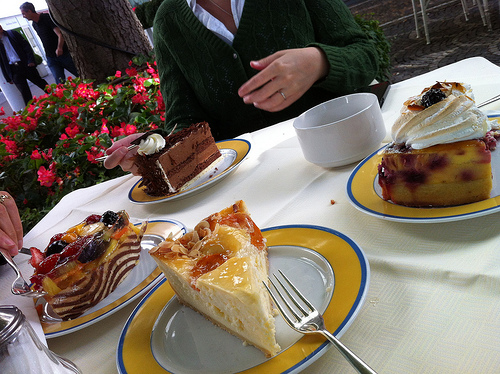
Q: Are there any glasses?
A: No, there are no glasses.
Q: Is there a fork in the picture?
A: Yes, there is a fork.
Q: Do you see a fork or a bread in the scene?
A: Yes, there is a fork.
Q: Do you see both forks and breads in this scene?
A: No, there is a fork but no breads.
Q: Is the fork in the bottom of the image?
A: Yes, the fork is in the bottom of the image.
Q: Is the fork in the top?
A: No, the fork is in the bottom of the image.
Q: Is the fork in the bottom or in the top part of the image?
A: The fork is in the bottom of the image.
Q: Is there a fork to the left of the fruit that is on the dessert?
A: Yes, there is a fork to the left of the fruit.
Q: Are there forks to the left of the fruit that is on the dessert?
A: Yes, there is a fork to the left of the fruit.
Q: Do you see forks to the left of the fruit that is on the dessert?
A: Yes, there is a fork to the left of the fruit.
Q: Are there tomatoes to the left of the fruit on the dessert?
A: No, there is a fork to the left of the fruit.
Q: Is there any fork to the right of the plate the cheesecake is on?
A: No, the fork is to the left of the plate.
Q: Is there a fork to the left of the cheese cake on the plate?
A: Yes, there is a fork to the left of the cheese cake.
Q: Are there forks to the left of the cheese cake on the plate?
A: Yes, there is a fork to the left of the cheese cake.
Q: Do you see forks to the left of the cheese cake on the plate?
A: Yes, there is a fork to the left of the cheese cake.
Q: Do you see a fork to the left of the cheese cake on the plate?
A: Yes, there is a fork to the left of the cheese cake.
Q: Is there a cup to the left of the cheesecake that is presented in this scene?
A: No, there is a fork to the left of the cheesecake.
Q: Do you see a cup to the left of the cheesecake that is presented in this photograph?
A: No, there is a fork to the left of the cheesecake.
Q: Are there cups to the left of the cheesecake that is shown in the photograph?
A: No, there is a fork to the left of the cheesecake.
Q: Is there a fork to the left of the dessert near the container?
A: Yes, there is a fork to the left of the dessert.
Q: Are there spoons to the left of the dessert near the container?
A: No, there is a fork to the left of the dessert.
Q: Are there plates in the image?
A: Yes, there is a plate.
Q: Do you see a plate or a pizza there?
A: Yes, there is a plate.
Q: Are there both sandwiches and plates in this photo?
A: No, there is a plate but no sandwiches.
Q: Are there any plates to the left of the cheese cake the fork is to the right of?
A: Yes, there is a plate to the left of the cheesecake.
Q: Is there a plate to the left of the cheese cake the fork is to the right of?
A: Yes, there is a plate to the left of the cheesecake.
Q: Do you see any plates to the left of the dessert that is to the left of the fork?
A: Yes, there is a plate to the left of the cheesecake.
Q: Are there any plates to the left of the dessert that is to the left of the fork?
A: Yes, there is a plate to the left of the cheesecake.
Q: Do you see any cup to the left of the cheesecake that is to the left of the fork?
A: No, there is a plate to the left of the cheese cake.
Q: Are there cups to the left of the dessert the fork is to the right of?
A: No, there is a plate to the left of the cheese cake.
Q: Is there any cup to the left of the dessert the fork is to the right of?
A: No, there is a plate to the left of the cheese cake.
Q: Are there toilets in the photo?
A: No, there are no toilets.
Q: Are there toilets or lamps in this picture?
A: No, there are no toilets or lamps.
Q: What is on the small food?
A: The icing is on the pie.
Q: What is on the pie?
A: The icing is on the pie.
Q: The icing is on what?
A: The icing is on the pie.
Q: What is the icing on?
A: The icing is on the pie.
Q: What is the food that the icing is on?
A: The food is a pie.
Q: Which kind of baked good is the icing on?
A: The icing is on the pie.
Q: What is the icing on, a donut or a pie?
A: The icing is on a pie.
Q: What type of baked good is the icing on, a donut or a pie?
A: The icing is on a pie.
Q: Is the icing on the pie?
A: Yes, the icing is on the pie.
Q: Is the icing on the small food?
A: Yes, the icing is on the pie.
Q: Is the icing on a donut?
A: No, the icing is on the pie.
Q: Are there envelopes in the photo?
A: No, there are no envelopes.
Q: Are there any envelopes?
A: No, there are no envelopes.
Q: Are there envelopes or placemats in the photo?
A: No, there are no envelopes or placemats.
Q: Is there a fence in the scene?
A: No, there are no fences.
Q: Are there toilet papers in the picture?
A: No, there are no toilet papers.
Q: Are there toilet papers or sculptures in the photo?
A: No, there are no toilet papers or sculptures.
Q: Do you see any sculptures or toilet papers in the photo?
A: No, there are no toilet papers or sculptures.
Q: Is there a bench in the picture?
A: No, there are no benches.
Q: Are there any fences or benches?
A: No, there are no benches or fences.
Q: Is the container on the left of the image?
A: Yes, the container is on the left of the image.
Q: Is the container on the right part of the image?
A: No, the container is on the left of the image.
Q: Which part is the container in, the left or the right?
A: The container is on the left of the image.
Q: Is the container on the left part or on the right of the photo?
A: The container is on the left of the image.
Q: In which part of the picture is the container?
A: The container is on the left of the image.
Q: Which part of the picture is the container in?
A: The container is on the left of the image.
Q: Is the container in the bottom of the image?
A: Yes, the container is in the bottom of the image.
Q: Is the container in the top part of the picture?
A: No, the container is in the bottom of the image.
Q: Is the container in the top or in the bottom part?
A: The container is in the bottom of the image.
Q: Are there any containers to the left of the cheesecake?
A: Yes, there is a container to the left of the cheesecake.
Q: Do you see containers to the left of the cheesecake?
A: Yes, there is a container to the left of the cheesecake.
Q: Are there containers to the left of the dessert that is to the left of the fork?
A: Yes, there is a container to the left of the cheesecake.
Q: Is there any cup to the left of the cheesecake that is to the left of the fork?
A: No, there is a container to the left of the cheese cake.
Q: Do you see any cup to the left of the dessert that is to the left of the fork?
A: No, there is a container to the left of the cheese cake.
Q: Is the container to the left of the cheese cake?
A: Yes, the container is to the left of the cheese cake.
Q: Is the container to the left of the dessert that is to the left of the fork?
A: Yes, the container is to the left of the cheese cake.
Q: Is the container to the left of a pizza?
A: No, the container is to the left of the cheese cake.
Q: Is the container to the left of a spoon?
A: No, the container is to the left of the plate.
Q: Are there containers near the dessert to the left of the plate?
A: Yes, there is a container near the dessert.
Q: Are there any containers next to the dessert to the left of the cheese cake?
A: Yes, there is a container next to the dessert.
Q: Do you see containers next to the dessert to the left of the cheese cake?
A: Yes, there is a container next to the dessert.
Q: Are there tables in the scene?
A: Yes, there is a table.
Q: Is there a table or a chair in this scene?
A: Yes, there is a table.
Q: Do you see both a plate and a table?
A: Yes, there are both a table and a plate.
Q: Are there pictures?
A: No, there are no pictures.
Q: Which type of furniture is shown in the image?
A: The furniture is a table.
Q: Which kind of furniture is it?
A: The piece of furniture is a table.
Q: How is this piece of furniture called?
A: That is a table.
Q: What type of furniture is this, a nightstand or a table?
A: That is a table.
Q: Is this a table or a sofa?
A: This is a table.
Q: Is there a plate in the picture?
A: Yes, there is a plate.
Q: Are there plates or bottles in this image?
A: Yes, there is a plate.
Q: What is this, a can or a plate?
A: This is a plate.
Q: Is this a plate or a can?
A: This is a plate.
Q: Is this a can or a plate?
A: This is a plate.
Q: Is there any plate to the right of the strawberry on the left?
A: Yes, there is a plate to the right of the strawberry.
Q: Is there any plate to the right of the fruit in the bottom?
A: Yes, there is a plate to the right of the strawberry.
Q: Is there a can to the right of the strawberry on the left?
A: No, there is a plate to the right of the strawberry.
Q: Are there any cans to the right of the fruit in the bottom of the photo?
A: No, there is a plate to the right of the strawberry.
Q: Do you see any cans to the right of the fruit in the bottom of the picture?
A: No, there is a plate to the right of the strawberry.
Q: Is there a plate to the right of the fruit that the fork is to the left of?
A: Yes, there is a plate to the right of the fruit.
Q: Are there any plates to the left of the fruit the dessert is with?
A: No, the plate is to the right of the fruit.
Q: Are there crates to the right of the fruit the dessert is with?
A: No, there is a plate to the right of the fruit.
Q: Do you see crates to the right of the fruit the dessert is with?
A: No, there is a plate to the right of the fruit.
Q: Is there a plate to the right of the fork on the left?
A: Yes, there is a plate to the right of the fork.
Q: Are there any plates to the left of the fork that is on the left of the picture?
A: No, the plate is to the right of the fork.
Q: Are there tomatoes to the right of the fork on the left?
A: No, there is a plate to the right of the fork.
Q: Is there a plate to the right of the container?
A: Yes, there is a plate to the right of the container.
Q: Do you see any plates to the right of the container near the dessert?
A: Yes, there is a plate to the right of the container.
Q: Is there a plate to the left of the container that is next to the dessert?
A: No, the plate is to the right of the container.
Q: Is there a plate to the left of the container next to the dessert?
A: No, the plate is to the right of the container.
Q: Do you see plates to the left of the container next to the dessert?
A: No, the plate is to the right of the container.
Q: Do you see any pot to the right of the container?
A: No, there is a plate to the right of the container.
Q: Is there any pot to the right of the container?
A: No, there is a plate to the right of the container.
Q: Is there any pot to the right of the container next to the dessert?
A: No, there is a plate to the right of the container.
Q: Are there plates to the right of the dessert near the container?
A: Yes, there is a plate to the right of the dessert.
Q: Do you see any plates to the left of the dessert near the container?
A: No, the plate is to the right of the dessert.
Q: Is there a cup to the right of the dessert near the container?
A: No, there is a plate to the right of the dessert.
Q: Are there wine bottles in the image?
A: No, there are no wine bottles.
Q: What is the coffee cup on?
A: The coffee cup is on the table.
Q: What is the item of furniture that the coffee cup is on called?
A: The piece of furniture is a table.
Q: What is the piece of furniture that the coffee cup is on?
A: The piece of furniture is a table.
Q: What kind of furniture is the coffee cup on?
A: The coffee cup is on the table.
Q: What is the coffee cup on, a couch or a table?
A: The coffee cup is on a table.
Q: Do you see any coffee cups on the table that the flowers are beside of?
A: Yes, there is a coffee cup on the table.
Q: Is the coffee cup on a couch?
A: No, the coffee cup is on the table.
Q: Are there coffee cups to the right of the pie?
A: Yes, there is a coffee cup to the right of the pie.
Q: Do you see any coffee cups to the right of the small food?
A: Yes, there is a coffee cup to the right of the pie.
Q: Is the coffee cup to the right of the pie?
A: Yes, the coffee cup is to the right of the pie.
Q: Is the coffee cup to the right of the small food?
A: Yes, the coffee cup is to the right of the pie.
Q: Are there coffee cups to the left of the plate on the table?
A: Yes, there is a coffee cup to the left of the plate.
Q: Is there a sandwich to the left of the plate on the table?
A: No, there is a coffee cup to the left of the plate.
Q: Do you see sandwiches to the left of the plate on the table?
A: No, there is a coffee cup to the left of the plate.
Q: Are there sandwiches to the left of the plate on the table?
A: No, there is a coffee cup to the left of the plate.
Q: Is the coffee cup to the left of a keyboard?
A: No, the coffee cup is to the left of the plate.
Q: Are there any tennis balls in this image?
A: No, there are no tennis balls.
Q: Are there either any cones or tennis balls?
A: No, there are no tennis balls or cones.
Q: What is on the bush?
A: The flowers are on the bush.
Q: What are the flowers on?
A: The flowers are on the shrub.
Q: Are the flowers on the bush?
A: Yes, the flowers are on the bush.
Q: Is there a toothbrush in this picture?
A: No, there are no toothbrushes.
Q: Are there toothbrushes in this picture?
A: No, there are no toothbrushes.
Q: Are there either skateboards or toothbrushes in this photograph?
A: No, there are no toothbrushes or skateboards.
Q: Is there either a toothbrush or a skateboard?
A: No, there are no toothbrushes or skateboards.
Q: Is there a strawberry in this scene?
A: Yes, there is a strawberry.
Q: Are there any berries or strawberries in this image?
A: Yes, there is a strawberry.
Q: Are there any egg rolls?
A: No, there are no egg rolls.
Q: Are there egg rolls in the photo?
A: No, there are no egg rolls.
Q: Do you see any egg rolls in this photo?
A: No, there are no egg rolls.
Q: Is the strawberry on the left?
A: Yes, the strawberry is on the left of the image.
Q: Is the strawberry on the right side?
A: No, the strawberry is on the left of the image.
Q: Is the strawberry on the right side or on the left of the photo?
A: The strawberry is on the left of the image.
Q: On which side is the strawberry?
A: The strawberry is on the left of the image.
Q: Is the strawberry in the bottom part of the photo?
A: Yes, the strawberry is in the bottom of the image.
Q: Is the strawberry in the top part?
A: No, the strawberry is in the bottom of the image.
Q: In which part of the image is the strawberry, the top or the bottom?
A: The strawberry is in the bottom of the image.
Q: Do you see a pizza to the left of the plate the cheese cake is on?
A: No, there is a strawberry to the left of the plate.